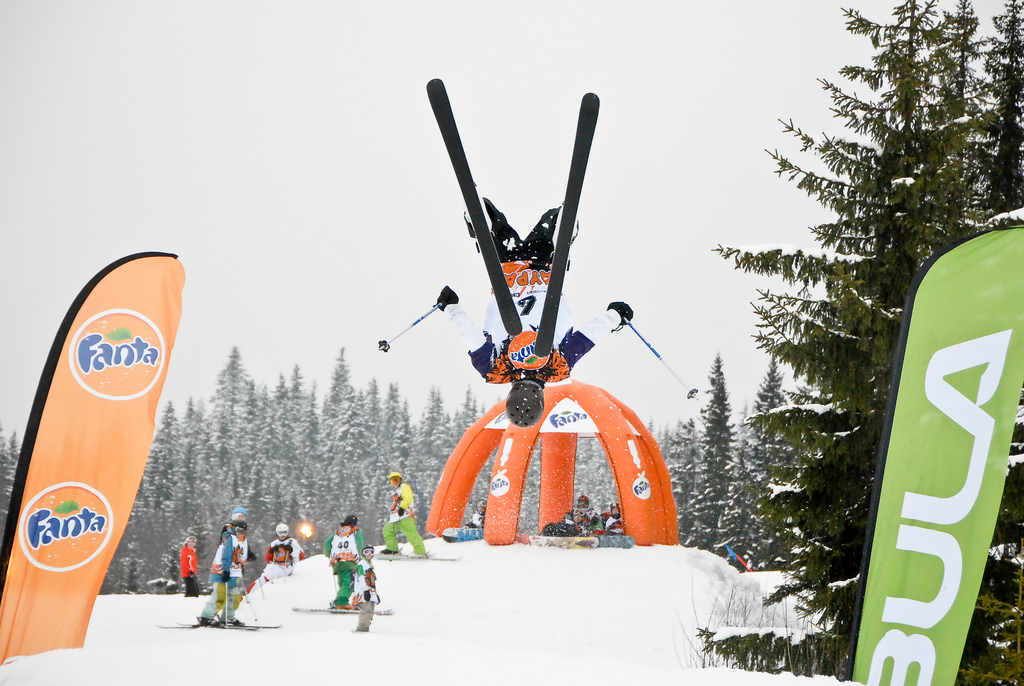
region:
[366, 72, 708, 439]
a snow skier is doing a flip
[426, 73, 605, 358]
the bottom of the skis is black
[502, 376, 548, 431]
the skier is wearing a black helmet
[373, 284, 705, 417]
the skier is holding ski poles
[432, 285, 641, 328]
the person is wearing black ski gloves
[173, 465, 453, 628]
skiers are watching the skier's flip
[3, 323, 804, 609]
evergreen trees are dusted with snow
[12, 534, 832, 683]
the ski slope's snow is groomed smooth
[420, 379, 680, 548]
an orange inflatable advertisement is on the slope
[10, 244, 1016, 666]
advertisement banners are on both sides of the slope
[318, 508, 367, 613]
skier in green jacket and pants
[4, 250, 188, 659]
orange post advertising Fanta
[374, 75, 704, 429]
skier doing flip in the air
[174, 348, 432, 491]
snow covered tree branches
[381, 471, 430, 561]
skier in green pants and yellow jacket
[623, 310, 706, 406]
blue and white ski pole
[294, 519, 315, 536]
glow of light on slope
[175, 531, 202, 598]
skier in red jacket and black pants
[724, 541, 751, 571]
blue flag on orange pole leaning forward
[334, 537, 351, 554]
black number 40 on skier's back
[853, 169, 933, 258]
green leaves on the tree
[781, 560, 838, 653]
green leaves on the tree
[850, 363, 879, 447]
green leaves on the tree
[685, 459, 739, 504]
green leaves on the tree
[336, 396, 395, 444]
green leaves on the tree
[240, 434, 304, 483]
green leaves on the tree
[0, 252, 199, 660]
large orange plastic banner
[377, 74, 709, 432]
person on skis flipping in air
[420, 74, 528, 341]
large long thin black ski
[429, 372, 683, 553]
large legged orange structure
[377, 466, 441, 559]
person on skis in green pants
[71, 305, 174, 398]
round fanta advertising sign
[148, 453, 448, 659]
people on the snow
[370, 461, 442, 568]
person wearing green pants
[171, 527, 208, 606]
woman has a red shirt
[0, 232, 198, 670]
an orange banner of FANTA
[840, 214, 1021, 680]
an green banner of BULA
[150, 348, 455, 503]
trees covered with snow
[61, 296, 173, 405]
the word FANTA in a circle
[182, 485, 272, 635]
skier wearing helmet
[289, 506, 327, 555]
a light is lit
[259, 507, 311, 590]
person wearing white helmet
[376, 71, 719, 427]
Skier upside down performing stunt.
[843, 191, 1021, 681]
Green and white ski gate sponsored by Bula.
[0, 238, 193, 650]
Orange ski gate sponsored by Fanta.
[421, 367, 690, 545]
Orange Fanta tent in background.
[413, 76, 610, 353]
The black bottom of two skis.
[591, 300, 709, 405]
A hand holding extended ski pole.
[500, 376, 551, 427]
Black ski helmet on skier.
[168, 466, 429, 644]
Skiers on the ski slope.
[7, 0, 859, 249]
Gray overcast cloudy skies.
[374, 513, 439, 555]
a person wearing green pants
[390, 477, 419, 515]
a person wearing a yellow shirt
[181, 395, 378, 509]
several trees covered with snow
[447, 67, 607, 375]
a person wearing snow skis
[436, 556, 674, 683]
the ground covered with snow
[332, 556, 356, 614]
a person wearing green pants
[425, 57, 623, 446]
a person upside down in the air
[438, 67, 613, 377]
a person wearing snow skis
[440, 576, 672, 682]
the ground covered with snow